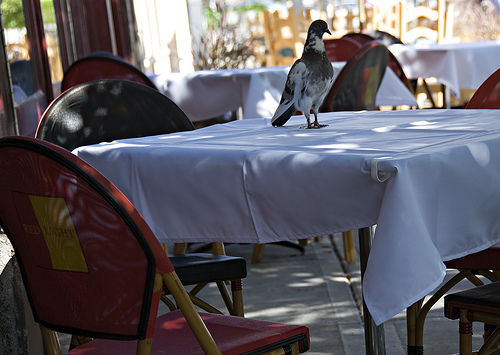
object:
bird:
[271, 19, 336, 129]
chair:
[0, 133, 311, 355]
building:
[0, 0, 132, 137]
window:
[0, 0, 43, 109]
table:
[69, 108, 500, 355]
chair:
[444, 281, 500, 355]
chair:
[32, 80, 247, 317]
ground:
[57, 225, 500, 355]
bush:
[193, 24, 258, 72]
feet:
[301, 108, 329, 129]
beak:
[324, 29, 332, 35]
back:
[0, 135, 174, 343]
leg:
[359, 225, 386, 355]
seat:
[68, 309, 310, 355]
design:
[27, 196, 90, 273]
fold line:
[243, 147, 263, 246]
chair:
[316, 33, 379, 113]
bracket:
[370, 156, 393, 183]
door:
[39, 0, 67, 100]